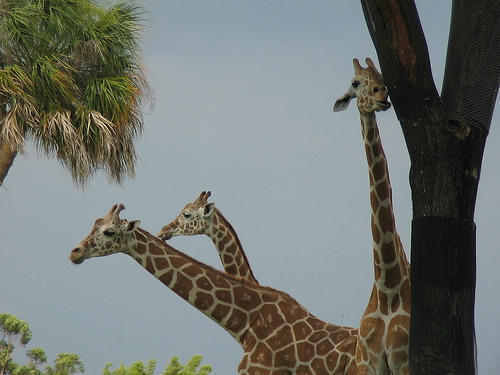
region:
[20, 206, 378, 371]
this is a giraffe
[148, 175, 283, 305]
this is a giraffe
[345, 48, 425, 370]
this is a giraffe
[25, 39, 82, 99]
these are leaves on a tree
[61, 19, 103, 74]
these are leaves on a tree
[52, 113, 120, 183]
these are leaves on a tree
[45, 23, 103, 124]
these are leaves on a tree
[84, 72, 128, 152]
these are leaves on a tree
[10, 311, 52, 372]
these are leaves on a tree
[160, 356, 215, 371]
these are leaves on a tree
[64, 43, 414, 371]
three giraffes standing next to tree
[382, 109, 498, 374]
brown tree trunk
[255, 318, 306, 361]
brown spots on giraffe fur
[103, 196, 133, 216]
ossicones on top of giraffe head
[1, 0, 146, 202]
green tree and brown tree trunk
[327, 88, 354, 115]
one giraffe ear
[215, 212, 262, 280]
brown hair giraffe mane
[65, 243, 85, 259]
giraffe nose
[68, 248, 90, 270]
giraffe mouth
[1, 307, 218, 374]
top of green trees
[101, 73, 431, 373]
three giraffes close together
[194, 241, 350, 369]
brown and white spots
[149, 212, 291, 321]
giraffe has brown mane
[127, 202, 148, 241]
giraffe has white ears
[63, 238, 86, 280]
giraffe has brown nose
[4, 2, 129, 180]
green and brown fronds of tree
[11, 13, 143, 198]
palm tree above giraffes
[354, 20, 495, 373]
brown trunk next to giraffes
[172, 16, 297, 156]
sky is blue and hazy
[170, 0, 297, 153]
no clouds in sky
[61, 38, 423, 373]
three giraffes standing next to each other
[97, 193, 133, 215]
ossicones on top of giraffes head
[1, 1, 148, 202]
green tree tops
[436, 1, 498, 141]
black netting material wrapped around tree branch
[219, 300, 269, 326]
brown spots on giraffe fur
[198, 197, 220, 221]
one giraffe ear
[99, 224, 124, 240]
one giraffe eye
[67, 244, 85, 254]
giraffe nostrils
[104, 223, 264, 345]
the giraffe has long neck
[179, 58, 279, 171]
the sky is overcast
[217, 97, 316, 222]
the sky is overcast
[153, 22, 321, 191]
the sky is overcast